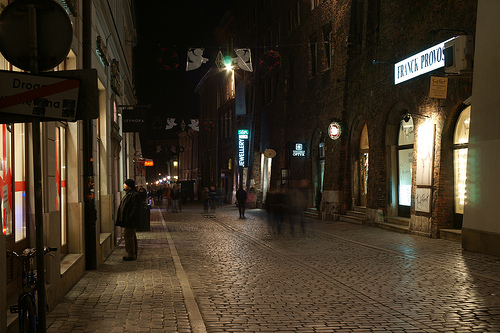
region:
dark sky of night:
[127, 1, 222, 114]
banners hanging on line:
[131, 39, 338, 73]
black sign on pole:
[119, 102, 151, 134]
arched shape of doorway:
[385, 98, 417, 220]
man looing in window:
[94, 176, 139, 262]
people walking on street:
[163, 172, 313, 240]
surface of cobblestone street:
[169, 196, 498, 331]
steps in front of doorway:
[338, 115, 373, 223]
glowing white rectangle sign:
[384, 35, 454, 85]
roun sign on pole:
[2, 0, 73, 331]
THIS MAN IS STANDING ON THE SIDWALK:
[102, 167, 152, 268]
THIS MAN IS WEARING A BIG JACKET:
[105, 180, 151, 228]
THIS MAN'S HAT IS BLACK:
[115, 173, 135, 189]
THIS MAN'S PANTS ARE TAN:
[117, 220, 138, 260]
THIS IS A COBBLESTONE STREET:
[162, 198, 493, 329]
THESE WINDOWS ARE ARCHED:
[375, 92, 485, 239]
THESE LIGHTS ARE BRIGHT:
[145, 157, 185, 187]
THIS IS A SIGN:
[0, 62, 86, 113]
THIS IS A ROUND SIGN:
[0, 0, 80, 81]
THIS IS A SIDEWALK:
[18, 202, 213, 332]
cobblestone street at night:
[206, 243, 401, 323]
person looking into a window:
[113, 172, 150, 264]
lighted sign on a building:
[391, 43, 460, 88]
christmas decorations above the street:
[180, 35, 259, 80]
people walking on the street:
[270, 169, 321, 251]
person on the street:
[228, 175, 250, 223]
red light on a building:
[137, 152, 159, 173]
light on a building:
[410, 113, 438, 172]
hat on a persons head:
[120, 176, 137, 188]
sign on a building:
[0, 3, 108, 138]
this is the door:
[384, 105, 416, 217]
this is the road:
[244, 230, 366, 330]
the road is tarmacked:
[267, 237, 397, 331]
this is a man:
[118, 174, 160, 255]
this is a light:
[218, 53, 240, 73]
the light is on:
[216, 54, 238, 71]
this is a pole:
[74, 139, 99, 254]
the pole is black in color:
[83, 133, 101, 274]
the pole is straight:
[84, 145, 96, 275]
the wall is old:
[335, 63, 381, 98]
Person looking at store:
[110, 167, 166, 265]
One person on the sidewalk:
[114, 170, 159, 271]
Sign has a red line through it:
[1, 63, 108, 133]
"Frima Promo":
[380, 40, 472, 111]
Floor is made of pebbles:
[198, 230, 463, 317]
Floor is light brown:
[205, 229, 446, 327]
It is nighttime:
[141, 5, 308, 113]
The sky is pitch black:
[141, 6, 199, 115]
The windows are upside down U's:
[336, 105, 472, 250]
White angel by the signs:
[181, 41, 217, 80]